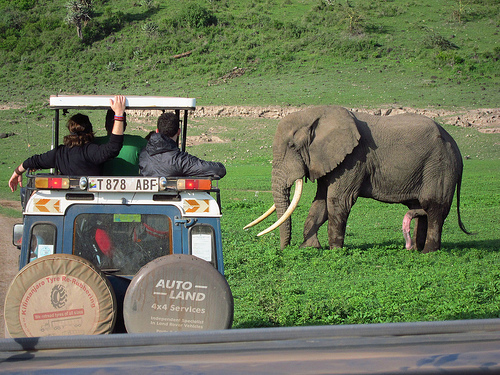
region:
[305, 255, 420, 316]
this is the grass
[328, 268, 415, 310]
the grass is green in color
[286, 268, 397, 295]
the grass is short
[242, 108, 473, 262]
this is an elephant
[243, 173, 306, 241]
these are two tusks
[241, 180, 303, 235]
the tusks are big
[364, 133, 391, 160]
the skin is grey in color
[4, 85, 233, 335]
this is a car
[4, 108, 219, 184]
these are three people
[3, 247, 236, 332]
these are two tires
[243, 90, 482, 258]
This is an elephant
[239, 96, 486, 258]
This is a grey elephant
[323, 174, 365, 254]
This is a leg of an elephant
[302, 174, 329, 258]
This is a leg of an elephant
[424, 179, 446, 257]
This is a leg of an elephant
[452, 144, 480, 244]
This is a tail of an elephant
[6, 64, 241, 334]
These are tourists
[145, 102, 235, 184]
This is a person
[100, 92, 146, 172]
This is a person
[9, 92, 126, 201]
This is a person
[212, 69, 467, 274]
the elephant is walking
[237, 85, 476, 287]
the elephant is standing on the grass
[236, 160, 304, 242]
the tusks are white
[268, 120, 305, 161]
the eye is open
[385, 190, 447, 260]
the penis is out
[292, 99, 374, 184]
the ear is wide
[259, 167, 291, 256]
the trunk is long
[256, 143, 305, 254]
the skin is wrinkled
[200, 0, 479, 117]
a grassy green hill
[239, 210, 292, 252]
the tusks are pointy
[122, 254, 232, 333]
dirty black spare tire cover with white text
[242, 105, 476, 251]
large grey male elephant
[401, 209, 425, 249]
large pink and grey elephant penis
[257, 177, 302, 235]
left ivory colored tusk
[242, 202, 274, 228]
right ivory colored tusk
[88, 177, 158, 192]
black and white license plate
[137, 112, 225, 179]
tourist wearing a black windbreaker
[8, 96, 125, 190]
woman in black shirt with red wristbands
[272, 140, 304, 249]
long grey elephant trunk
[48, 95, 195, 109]
flat white vehicle roof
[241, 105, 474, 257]
gray elephant with tusks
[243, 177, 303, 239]
ivory tusks on elephant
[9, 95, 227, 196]
people in vehicle watching elephant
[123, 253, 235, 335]
wheel with cover on back of vehicle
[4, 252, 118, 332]
covered wheel on back of vehicle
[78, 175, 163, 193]
license tag on vehicle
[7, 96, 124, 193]
person holding onto top of vehicle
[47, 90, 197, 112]
white top of vehicle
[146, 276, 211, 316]
advertisement on wheel cover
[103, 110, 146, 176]
person in green shirt